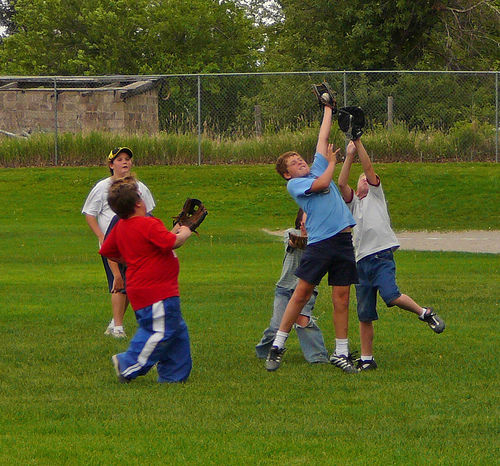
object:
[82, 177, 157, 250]
shirt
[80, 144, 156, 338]
boy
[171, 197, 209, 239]
baseball glove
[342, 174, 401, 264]
shirt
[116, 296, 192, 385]
pants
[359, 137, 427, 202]
ground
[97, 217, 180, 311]
t-shirt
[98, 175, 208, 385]
boy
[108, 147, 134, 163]
hat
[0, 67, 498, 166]
fence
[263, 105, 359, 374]
boy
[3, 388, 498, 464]
grass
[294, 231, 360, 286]
shorts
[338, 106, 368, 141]
glove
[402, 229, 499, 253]
gravel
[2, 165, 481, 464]
field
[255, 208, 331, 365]
boy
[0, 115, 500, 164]
grass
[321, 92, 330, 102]
ball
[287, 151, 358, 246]
shirt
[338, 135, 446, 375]
boy